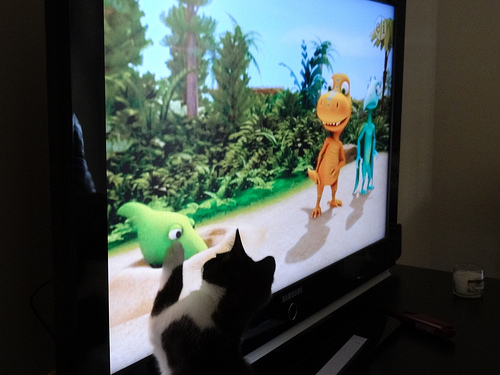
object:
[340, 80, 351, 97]
eyes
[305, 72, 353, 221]
animal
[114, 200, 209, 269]
animal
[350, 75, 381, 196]
animal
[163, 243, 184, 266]
paws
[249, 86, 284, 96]
building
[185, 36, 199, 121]
tree base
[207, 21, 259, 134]
plant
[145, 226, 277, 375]
cat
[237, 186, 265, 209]
grass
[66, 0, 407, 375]
tv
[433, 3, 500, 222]
wall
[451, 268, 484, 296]
candle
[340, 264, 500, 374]
counter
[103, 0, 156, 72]
tree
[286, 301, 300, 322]
power button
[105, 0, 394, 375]
cartoons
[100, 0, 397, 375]
screen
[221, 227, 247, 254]
ear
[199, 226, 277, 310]
head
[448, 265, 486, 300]
stand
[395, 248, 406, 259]
corner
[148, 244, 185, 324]
leg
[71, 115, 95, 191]
blob